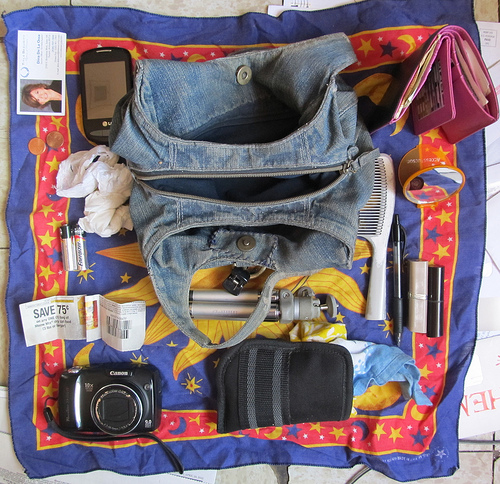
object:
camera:
[58, 362, 162, 435]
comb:
[357, 153, 395, 321]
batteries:
[59, 223, 89, 271]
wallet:
[369, 24, 500, 146]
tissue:
[56, 145, 134, 238]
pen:
[391, 214, 407, 349]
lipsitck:
[427, 266, 444, 338]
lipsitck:
[408, 261, 429, 333]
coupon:
[19, 294, 146, 353]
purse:
[107, 32, 381, 350]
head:
[23, 84, 50, 108]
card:
[16, 30, 66, 117]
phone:
[79, 46, 134, 147]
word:
[34, 305, 55, 318]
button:
[236, 65, 252, 85]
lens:
[90, 384, 142, 436]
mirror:
[405, 168, 463, 205]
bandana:
[0, 0, 486, 481]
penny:
[28, 137, 46, 155]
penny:
[46, 131, 64, 148]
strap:
[43, 406, 184, 474]